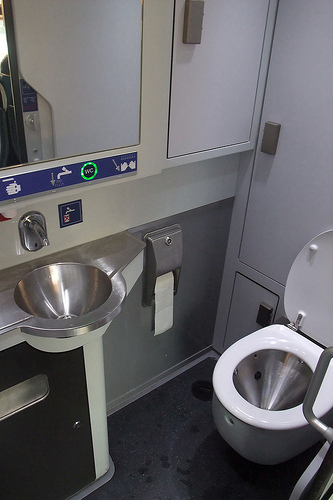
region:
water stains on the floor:
[102, 397, 246, 497]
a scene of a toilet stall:
[1, 1, 320, 498]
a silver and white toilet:
[198, 303, 330, 479]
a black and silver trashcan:
[1, 338, 102, 498]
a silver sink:
[0, 231, 149, 354]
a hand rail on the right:
[292, 337, 331, 447]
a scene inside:
[1, 1, 331, 491]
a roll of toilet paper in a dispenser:
[140, 227, 185, 347]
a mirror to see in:
[0, 0, 141, 173]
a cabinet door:
[159, 2, 271, 161]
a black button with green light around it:
[79, 161, 98, 180]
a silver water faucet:
[15, 209, 50, 253]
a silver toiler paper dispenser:
[143, 221, 183, 336]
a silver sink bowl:
[9, 260, 126, 340]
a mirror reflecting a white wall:
[0, 0, 143, 171]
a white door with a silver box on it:
[165, 1, 269, 159]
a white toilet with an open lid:
[211, 230, 331, 469]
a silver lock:
[73, 420, 82, 429]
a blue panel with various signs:
[0, 151, 137, 203]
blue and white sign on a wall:
[58, 198, 82, 227]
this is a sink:
[21, 247, 113, 317]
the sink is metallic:
[24, 259, 104, 308]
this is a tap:
[24, 211, 53, 249]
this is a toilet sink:
[213, 345, 306, 433]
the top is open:
[226, 343, 308, 411]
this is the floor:
[143, 414, 204, 481]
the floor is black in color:
[136, 411, 199, 489]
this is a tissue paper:
[152, 274, 176, 332]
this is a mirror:
[7, 6, 127, 141]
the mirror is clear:
[12, 17, 122, 138]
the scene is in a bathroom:
[2, 1, 326, 499]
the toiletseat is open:
[223, 324, 317, 422]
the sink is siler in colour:
[3, 265, 118, 317]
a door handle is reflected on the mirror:
[24, 90, 58, 166]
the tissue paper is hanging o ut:
[152, 268, 175, 337]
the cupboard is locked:
[237, 3, 302, 247]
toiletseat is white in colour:
[228, 383, 297, 414]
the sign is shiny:
[73, 160, 106, 178]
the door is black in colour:
[11, 445, 76, 471]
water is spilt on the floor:
[140, 450, 200, 495]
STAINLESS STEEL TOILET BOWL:
[212, 321, 332, 459]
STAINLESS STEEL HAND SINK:
[4, 265, 125, 350]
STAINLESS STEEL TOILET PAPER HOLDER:
[142, 225, 190, 312]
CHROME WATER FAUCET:
[16, 213, 50, 254]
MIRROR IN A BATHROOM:
[2, 2, 152, 164]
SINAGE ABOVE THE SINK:
[2, 167, 150, 203]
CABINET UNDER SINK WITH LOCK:
[0, 347, 107, 498]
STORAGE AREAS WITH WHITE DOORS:
[157, 4, 332, 177]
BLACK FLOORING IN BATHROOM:
[126, 394, 249, 499]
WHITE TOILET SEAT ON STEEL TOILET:
[212, 225, 332, 435]